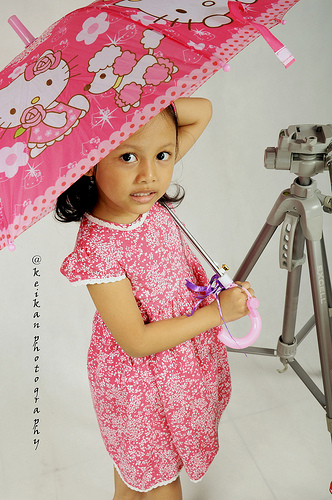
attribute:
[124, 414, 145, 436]
flower — pink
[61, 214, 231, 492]
dress — red, pink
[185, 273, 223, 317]
ribbon — purple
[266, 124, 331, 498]
tripod — silver, grey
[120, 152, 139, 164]
eyes — brown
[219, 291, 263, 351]
handle — pink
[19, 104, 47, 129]
rose — pink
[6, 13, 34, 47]
tip — pink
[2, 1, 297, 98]
umbrella — pink, hello kitty theme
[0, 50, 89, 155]
hello kitty — cartoon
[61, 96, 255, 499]
girl — posing, female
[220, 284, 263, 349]
handle — pink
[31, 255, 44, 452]
copyright letters — in black print, black